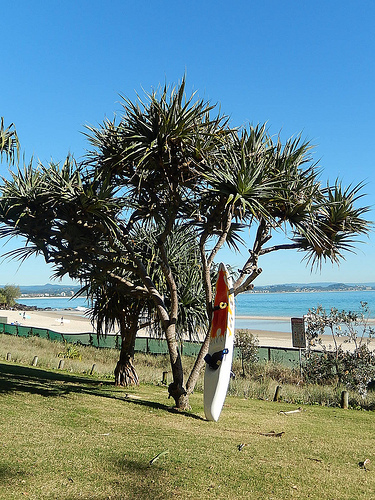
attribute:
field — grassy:
[2, 352, 373, 497]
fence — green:
[0, 320, 370, 385]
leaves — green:
[152, 123, 193, 161]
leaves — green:
[2, 66, 370, 331]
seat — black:
[201, 348, 226, 372]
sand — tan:
[14, 313, 103, 336]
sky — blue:
[271, 22, 313, 68]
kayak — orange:
[185, 252, 260, 432]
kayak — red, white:
[204, 261, 236, 420]